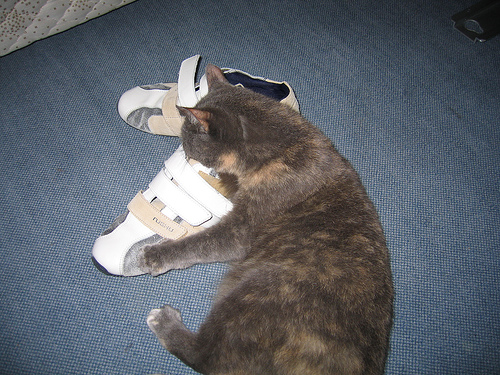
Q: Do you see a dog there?
A: No, there are no dogs.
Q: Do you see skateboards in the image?
A: No, there are no skateboards.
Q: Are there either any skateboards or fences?
A: No, there are no skateboards or fences.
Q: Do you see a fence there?
A: No, there are no fences.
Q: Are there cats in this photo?
A: Yes, there is a cat.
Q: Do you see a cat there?
A: Yes, there is a cat.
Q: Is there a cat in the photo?
A: Yes, there is a cat.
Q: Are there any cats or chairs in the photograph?
A: Yes, there is a cat.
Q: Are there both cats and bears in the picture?
A: No, there is a cat but no bears.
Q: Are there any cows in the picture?
A: No, there are no cows.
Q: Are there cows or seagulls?
A: No, there are no cows or seagulls.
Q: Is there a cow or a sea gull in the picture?
A: No, there are no cows or seagulls.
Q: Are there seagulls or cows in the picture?
A: No, there are no cows or seagulls.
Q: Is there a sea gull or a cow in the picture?
A: No, there are no cows or seagulls.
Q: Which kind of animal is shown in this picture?
A: The animal is a cat.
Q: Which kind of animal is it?
A: The animal is a cat.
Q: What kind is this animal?
A: This is a cat.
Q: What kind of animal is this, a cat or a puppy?
A: This is a cat.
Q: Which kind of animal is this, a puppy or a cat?
A: This is a cat.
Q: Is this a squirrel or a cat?
A: This is a cat.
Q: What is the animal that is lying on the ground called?
A: The animal is a cat.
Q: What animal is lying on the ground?
A: The animal is a cat.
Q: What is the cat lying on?
A: The cat is lying on the ground.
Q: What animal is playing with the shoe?
A: The cat is playing with the shoe.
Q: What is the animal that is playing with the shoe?
A: The animal is a cat.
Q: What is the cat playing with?
A: The cat is playing with the shoe.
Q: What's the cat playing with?
A: The cat is playing with the shoe.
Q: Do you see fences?
A: No, there are no fences.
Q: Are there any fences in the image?
A: No, there are no fences.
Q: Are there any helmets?
A: No, there are no helmets.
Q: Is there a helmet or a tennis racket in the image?
A: No, there are no helmets or rackets.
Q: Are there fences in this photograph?
A: No, there are no fences.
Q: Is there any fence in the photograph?
A: No, there are no fences.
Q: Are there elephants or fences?
A: No, there are no fences or elephants.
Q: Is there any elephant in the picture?
A: No, there are no elephants.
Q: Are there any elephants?
A: No, there are no elephants.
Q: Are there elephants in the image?
A: No, there are no elephants.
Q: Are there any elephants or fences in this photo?
A: No, there are no elephants or fences.